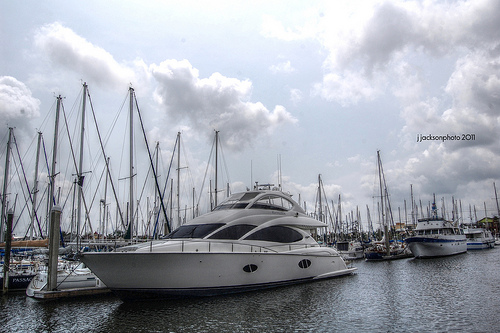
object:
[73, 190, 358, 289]
yacht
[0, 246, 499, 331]
water